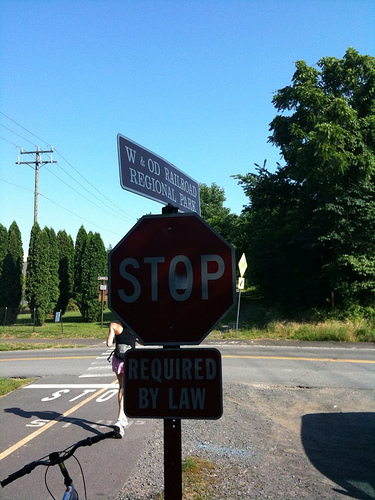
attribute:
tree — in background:
[24, 219, 50, 325]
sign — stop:
[104, 130, 240, 443]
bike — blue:
[0, 429, 118, 498]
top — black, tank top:
[108, 320, 131, 339]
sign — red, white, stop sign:
[105, 211, 247, 347]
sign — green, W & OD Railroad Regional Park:
[70, 203, 329, 371]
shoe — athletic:
[83, 389, 139, 442]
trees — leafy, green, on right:
[200, 44, 374, 317]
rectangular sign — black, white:
[108, 134, 216, 218]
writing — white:
[130, 353, 217, 409]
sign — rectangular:
[123, 346, 223, 420]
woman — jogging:
[105, 316, 138, 438]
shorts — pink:
[110, 353, 123, 373]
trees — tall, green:
[0, 220, 108, 323]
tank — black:
[112, 320, 136, 347]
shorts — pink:
[109, 350, 128, 377]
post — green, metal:
[162, 413, 184, 496]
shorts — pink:
[106, 355, 132, 374]